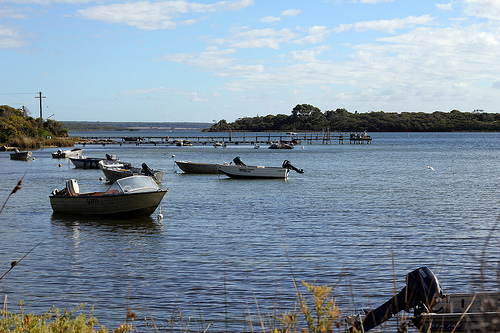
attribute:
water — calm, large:
[1, 127, 499, 330]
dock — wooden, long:
[58, 124, 376, 156]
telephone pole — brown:
[31, 87, 49, 133]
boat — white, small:
[215, 154, 298, 184]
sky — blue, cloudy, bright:
[1, 1, 499, 122]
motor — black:
[338, 262, 448, 332]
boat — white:
[46, 164, 162, 223]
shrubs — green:
[1, 105, 62, 138]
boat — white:
[201, 149, 305, 189]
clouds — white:
[76, 3, 493, 132]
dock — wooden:
[2, 117, 384, 159]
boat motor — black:
[340, 266, 453, 331]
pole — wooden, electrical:
[34, 85, 45, 142]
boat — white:
[217, 149, 307, 184]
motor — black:
[276, 157, 308, 178]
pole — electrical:
[34, 84, 45, 152]